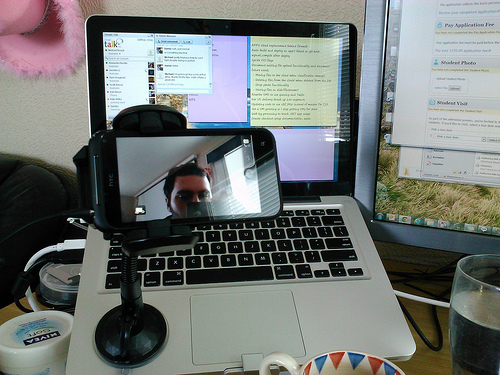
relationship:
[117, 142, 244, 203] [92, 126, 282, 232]
screen on smartphone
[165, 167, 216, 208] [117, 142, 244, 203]
face on screen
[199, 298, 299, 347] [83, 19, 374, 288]
touchpad on computer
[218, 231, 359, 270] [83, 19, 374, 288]
keyboard on computer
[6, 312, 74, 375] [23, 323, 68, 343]
container of niveacream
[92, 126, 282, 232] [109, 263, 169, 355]
smartphone attached to stand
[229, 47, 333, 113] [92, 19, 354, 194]
programs on screen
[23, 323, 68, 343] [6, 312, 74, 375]
tub of lotion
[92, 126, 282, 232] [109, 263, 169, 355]
smartphone has stand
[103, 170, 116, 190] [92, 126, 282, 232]
htc on smartphone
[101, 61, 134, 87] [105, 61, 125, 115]
googletalk on contactlist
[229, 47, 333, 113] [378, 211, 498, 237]
programs in taskbar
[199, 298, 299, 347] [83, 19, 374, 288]
trackpad for laptop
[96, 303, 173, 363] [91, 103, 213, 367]
base of standhand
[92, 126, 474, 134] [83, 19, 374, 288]
smartphone attached to computer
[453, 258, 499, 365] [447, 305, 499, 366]
glass has water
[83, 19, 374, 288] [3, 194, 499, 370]
laptop on desk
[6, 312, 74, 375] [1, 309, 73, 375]
container has niveacream